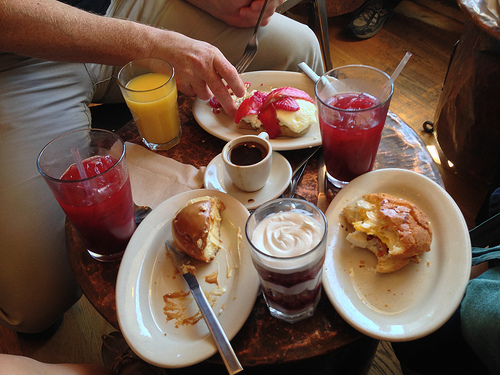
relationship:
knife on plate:
[164, 236, 244, 373] [115, 187, 262, 370]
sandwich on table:
[342, 193, 432, 273] [64, 69, 443, 368]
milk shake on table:
[244, 197, 328, 323] [64, 69, 443, 368]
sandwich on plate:
[342, 193, 433, 274] [320, 165, 473, 340]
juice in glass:
[56, 155, 135, 253] [36, 125, 139, 264]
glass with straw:
[36, 125, 139, 264] [72, 143, 92, 198]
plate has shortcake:
[190, 68, 348, 152] [210, 84, 317, 138]